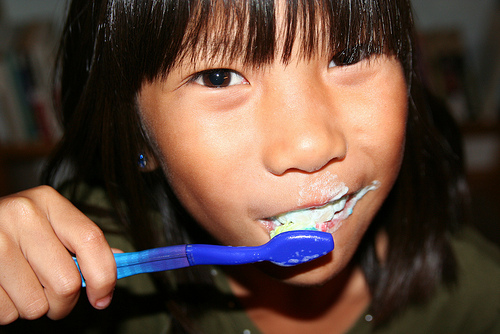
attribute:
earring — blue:
[137, 149, 147, 169]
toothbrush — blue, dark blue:
[70, 216, 338, 286]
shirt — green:
[1, 173, 500, 331]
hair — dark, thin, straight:
[36, 1, 473, 332]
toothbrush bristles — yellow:
[266, 223, 311, 236]